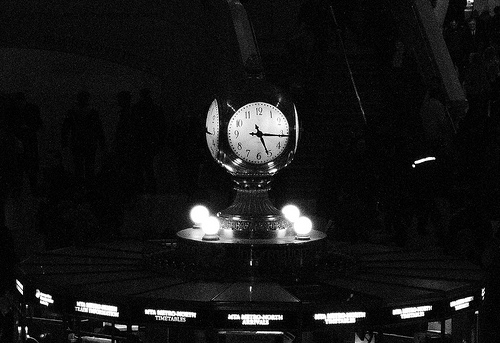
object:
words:
[240, 319, 273, 326]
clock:
[226, 100, 288, 167]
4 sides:
[201, 90, 302, 179]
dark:
[28, 25, 159, 173]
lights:
[199, 212, 223, 242]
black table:
[0, 234, 500, 342]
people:
[57, 82, 109, 178]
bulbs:
[294, 215, 315, 239]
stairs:
[356, 270, 471, 291]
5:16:
[248, 122, 293, 160]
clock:
[206, 100, 221, 156]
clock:
[294, 106, 300, 154]